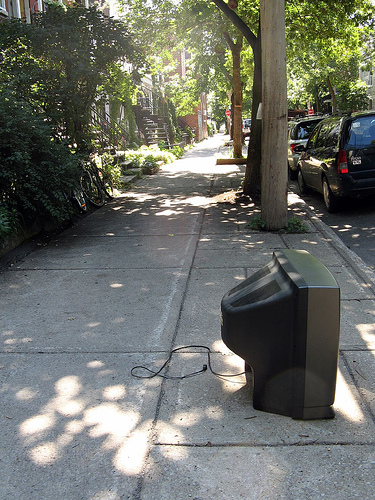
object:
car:
[296, 109, 374, 214]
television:
[218, 249, 341, 421]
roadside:
[0, 133, 374, 500]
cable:
[129, 343, 245, 383]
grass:
[290, 221, 301, 232]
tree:
[26, 6, 147, 163]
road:
[299, 184, 375, 276]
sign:
[307, 109, 314, 114]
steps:
[146, 128, 170, 142]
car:
[286, 117, 329, 180]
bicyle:
[79, 154, 114, 208]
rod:
[81, 97, 131, 161]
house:
[0, 1, 42, 27]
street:
[0, 133, 370, 500]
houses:
[159, 4, 210, 142]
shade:
[133, 168, 235, 199]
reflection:
[164, 153, 224, 174]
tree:
[176, 1, 247, 163]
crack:
[170, 267, 196, 347]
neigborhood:
[3, 4, 375, 249]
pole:
[261, 1, 288, 232]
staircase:
[127, 80, 175, 150]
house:
[82, 0, 153, 91]